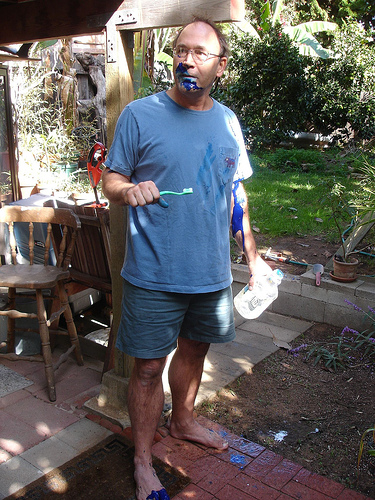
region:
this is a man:
[70, 16, 307, 498]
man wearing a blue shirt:
[100, 67, 261, 345]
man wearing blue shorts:
[109, 254, 268, 379]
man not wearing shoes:
[111, 380, 233, 496]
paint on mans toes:
[144, 474, 179, 498]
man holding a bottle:
[225, 242, 305, 335]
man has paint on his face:
[165, 61, 211, 106]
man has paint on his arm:
[216, 162, 261, 253]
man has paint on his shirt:
[180, 139, 255, 217]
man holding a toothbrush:
[135, 159, 212, 215]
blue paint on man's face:
[168, 61, 204, 95]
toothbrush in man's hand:
[116, 165, 198, 211]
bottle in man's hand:
[235, 254, 289, 322]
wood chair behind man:
[0, 201, 86, 402]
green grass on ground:
[240, 143, 368, 234]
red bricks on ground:
[160, 414, 357, 499]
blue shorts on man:
[118, 280, 236, 365]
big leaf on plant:
[259, 9, 338, 63]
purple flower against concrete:
[289, 295, 369, 372]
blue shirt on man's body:
[97, 88, 269, 289]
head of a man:
[159, 17, 253, 104]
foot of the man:
[178, 407, 232, 453]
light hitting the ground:
[24, 452, 83, 499]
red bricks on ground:
[227, 441, 293, 488]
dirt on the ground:
[262, 389, 321, 428]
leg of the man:
[124, 353, 182, 453]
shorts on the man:
[118, 285, 246, 364]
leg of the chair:
[22, 284, 71, 403]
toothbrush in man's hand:
[156, 171, 208, 209]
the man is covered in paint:
[106, 151, 276, 277]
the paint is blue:
[183, 157, 236, 193]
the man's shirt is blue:
[126, 131, 235, 262]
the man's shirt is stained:
[190, 147, 254, 204]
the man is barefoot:
[92, 417, 244, 479]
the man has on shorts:
[105, 282, 258, 360]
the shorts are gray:
[118, 271, 224, 349]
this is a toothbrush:
[108, 174, 222, 214]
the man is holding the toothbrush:
[145, 139, 207, 229]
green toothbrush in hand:
[157, 177, 192, 200]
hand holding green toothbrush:
[125, 179, 200, 215]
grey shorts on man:
[121, 280, 251, 356]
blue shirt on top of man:
[99, 98, 257, 296]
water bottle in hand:
[236, 265, 288, 324]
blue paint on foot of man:
[141, 476, 174, 499]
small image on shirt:
[215, 153, 235, 174]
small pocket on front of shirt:
[213, 139, 243, 167]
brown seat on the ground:
[0, 208, 90, 397]